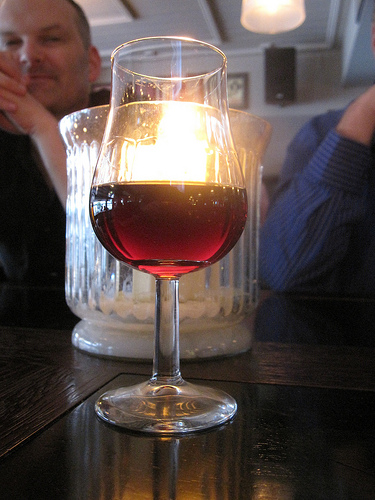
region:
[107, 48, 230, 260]
GLASS OF RED WINE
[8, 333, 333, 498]
BROWN WOODEN TABLE UNDER GLASS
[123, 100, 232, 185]
LIT CANDLE BEHIND WINE GLASS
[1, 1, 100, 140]
MAN WITH SHAVED HEAD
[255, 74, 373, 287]
BLUE PIN STRIPED SHIRT ARM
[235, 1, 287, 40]
LIT LAMP ON ROOF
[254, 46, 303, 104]
BLACK SPEAKER ON REAR WALL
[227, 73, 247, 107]
PICTURE IN FRAME ON WALL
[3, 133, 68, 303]
BLACK SHIRT OF MAN ON LEFT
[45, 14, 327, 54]
WHITE WOODEN CEILING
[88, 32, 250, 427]
the wine glass is filled with red liquid and has the light shinning through it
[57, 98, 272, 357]
the candel is behind the wine glass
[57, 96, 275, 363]
the candel is lit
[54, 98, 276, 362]
the candel is white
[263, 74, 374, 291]
this man is wearing a blue shirt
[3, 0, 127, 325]
this man is wearing a black shirt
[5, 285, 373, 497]
the table is made of a stainned wood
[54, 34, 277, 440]
the wine glass and the candle sit next to each other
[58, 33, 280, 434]
the candel and the wine glass sit on top of the table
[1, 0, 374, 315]
you can see two people in this picture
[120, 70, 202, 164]
this is a glass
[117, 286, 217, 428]
the stand is tall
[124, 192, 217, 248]
the glass s half full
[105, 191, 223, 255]
the wine is red in color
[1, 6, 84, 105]
this is a man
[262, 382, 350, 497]
this is a table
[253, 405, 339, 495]
the table is made of glass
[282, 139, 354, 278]
the shirt is blue in color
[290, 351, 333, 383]
the table is wooden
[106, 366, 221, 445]
the stand is flat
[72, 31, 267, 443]
a clear wine glass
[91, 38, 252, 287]
red wine in glass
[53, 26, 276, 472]
a candle is behind the wine glass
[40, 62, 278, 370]
the candle is lit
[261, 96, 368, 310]
a blue striped shirt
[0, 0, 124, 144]
the man is smiling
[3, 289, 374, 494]
the table is dark colored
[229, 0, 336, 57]
a light on the ceiling is lit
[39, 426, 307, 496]
a reflection on the table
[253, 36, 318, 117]
a speaker on the wall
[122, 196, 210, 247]
The wine is red.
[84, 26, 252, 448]
The wine glass is the focus of the picture.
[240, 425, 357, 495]
The table is dark brown.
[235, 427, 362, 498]
The table is made of wood.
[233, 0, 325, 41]
A light is hanging from the ceiling.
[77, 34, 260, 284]
The wine glass is only one third full.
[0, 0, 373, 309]
Two people are in the background.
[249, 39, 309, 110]
A speaker is on the wall.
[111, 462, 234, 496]
Light is reflecting on the table.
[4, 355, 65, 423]
The grain of the table wood is showing.